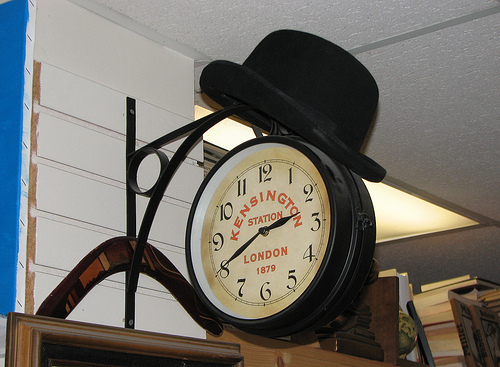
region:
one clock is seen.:
[157, 135, 400, 328]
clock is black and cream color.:
[110, 85, 377, 300]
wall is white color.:
[48, 63, 103, 158]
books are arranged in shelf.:
[399, 257, 499, 364]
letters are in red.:
[211, 178, 303, 281]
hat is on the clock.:
[191, 27, 383, 194]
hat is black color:
[211, 46, 388, 186]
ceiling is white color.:
[399, 39, 498, 166]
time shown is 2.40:
[183, 171, 323, 301]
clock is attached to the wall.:
[91, 96, 158, 318]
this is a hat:
[232, 20, 387, 140]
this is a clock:
[186, 143, 383, 348]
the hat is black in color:
[299, 60, 353, 117]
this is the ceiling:
[406, 90, 466, 169]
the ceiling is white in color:
[420, 127, 467, 184]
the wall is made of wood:
[47, 68, 103, 229]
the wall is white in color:
[50, 111, 90, 202]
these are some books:
[410, 265, 491, 360]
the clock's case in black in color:
[338, 205, 353, 270]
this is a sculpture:
[349, 306, 384, 357]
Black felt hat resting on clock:
[216, 48, 363, 151]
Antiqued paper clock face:
[219, 193, 314, 273]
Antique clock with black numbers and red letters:
[183, 166, 345, 341]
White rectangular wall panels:
[41, 117, 88, 224]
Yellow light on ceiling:
[400, 155, 462, 260]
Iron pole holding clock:
[116, 113, 174, 272]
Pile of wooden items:
[406, 262, 481, 364]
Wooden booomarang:
[42, 213, 185, 328]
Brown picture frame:
[10, 310, 130, 365]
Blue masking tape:
[8, 12, 33, 232]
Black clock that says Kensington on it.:
[182, 144, 379, 335]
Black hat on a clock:
[198, 27, 395, 181]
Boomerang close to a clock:
[38, 230, 225, 339]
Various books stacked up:
[418, 278, 498, 358]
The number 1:
[285, 166, 293, 183]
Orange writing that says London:
[237, 245, 292, 263]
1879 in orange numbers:
[254, 263, 276, 274]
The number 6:
[257, 279, 274, 300]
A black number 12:
[256, 164, 272, 182]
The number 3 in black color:
[310, 210, 321, 232]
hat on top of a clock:
[47, 13, 477, 346]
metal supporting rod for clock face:
[75, 80, 240, 340]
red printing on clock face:
[185, 140, 345, 320]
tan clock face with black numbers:
[180, 136, 355, 321]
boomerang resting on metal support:
[30, 225, 230, 340]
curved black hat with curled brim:
[171, 20, 427, 185]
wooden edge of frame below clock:
[1, 307, 241, 357]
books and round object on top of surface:
[341, 261, 491, 356]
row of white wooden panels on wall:
[30, 55, 210, 341]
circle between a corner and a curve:
[115, 140, 190, 203]